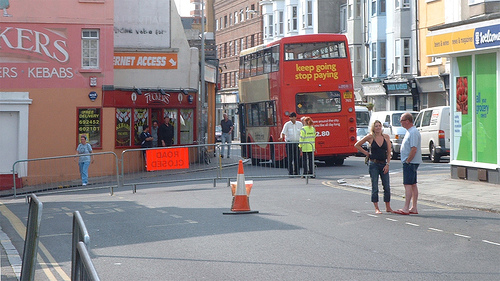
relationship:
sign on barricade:
[140, 146, 194, 172] [25, 122, 361, 200]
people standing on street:
[355, 120, 393, 214] [1, 150, 498, 280]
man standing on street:
[393, 111, 425, 216] [1, 150, 498, 280]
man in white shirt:
[393, 113, 422, 215] [395, 125, 422, 161]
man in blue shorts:
[393, 113, 422, 215] [401, 162, 418, 184]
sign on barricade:
[144, 147, 190, 171] [9, 141, 316, 201]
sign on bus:
[295, 63, 337, 81] [235, 32, 365, 170]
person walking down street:
[70, 132, 100, 192] [18, 142, 480, 270]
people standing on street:
[353, 114, 422, 216] [77, 184, 499, 278]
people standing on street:
[279, 109, 316, 178] [205, 138, 429, 172]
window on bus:
[295, 91, 344, 112] [236, 31, 361, 161]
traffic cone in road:
[222, 158, 259, 214] [0, 138, 497, 279]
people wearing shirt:
[355, 120, 393, 214] [369, 139, 389, 162]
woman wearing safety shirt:
[296, 114, 320, 172] [300, 124, 317, 152]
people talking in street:
[355, 120, 393, 214] [20, 157, 476, 278]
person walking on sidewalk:
[70, 132, 100, 192] [0, 136, 243, 196]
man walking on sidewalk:
[219, 113, 233, 160] [100, 143, 243, 183]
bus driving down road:
[208, 26, 374, 181] [15, 164, 485, 273]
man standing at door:
[158, 113, 175, 150] [152, 109, 173, 159]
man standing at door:
[152, 119, 161, 153] [152, 109, 173, 159]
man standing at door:
[138, 123, 153, 147] [152, 109, 173, 159]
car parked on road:
[402, 106, 452, 158] [0, 138, 497, 279]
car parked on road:
[367, 107, 413, 149] [0, 138, 497, 279]